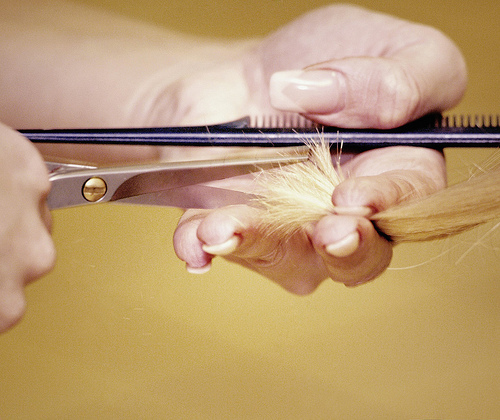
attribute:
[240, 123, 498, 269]
hair — blonde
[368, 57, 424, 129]
knuckle — taut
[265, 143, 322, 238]
ends — split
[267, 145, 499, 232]
hair — blond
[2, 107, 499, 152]
comb — black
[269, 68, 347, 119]
fingernail — well manicured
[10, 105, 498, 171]
comb — black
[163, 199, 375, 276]
nails — long, finger nails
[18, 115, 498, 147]
comb — black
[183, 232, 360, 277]
nails — manicured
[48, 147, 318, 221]
scissors — high end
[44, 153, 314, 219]
scissors — stainless steel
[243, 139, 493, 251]
hair — blond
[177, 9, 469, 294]
fingers — dry skin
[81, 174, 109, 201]
screw — gold colored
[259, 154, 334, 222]
ends — blond